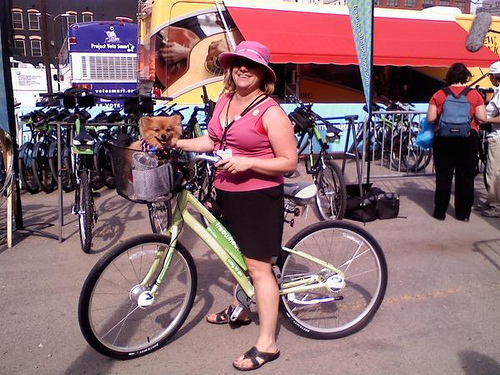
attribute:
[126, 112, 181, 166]
dog — brown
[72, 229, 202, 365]
tire — black , thin 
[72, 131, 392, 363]
bike — light green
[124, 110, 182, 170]
pomeranian — light brown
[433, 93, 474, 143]
bookbag — blue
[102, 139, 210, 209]
basket — small , black 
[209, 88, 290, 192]
shirt — pink, sleeveless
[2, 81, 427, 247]
bikes — parked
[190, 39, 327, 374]
woman — foreground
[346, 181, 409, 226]
bag — large , black 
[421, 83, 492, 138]
shirt sleeve — red, short sleeve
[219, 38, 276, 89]
hat — round, pink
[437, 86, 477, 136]
backpack — blue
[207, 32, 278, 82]
hat — pink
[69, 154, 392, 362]
bicycle — yellow